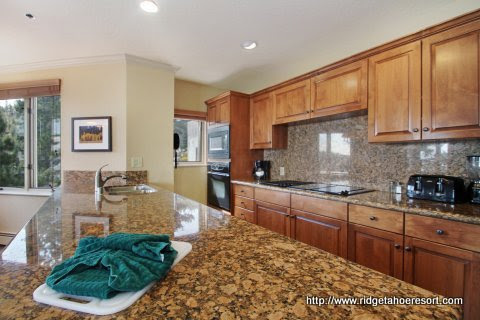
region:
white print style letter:
[305, 293, 311, 305]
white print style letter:
[315, 295, 326, 308]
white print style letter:
[332, 295, 342, 303]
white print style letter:
[340, 295, 350, 304]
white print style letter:
[348, 296, 358, 305]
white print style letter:
[454, 295, 462, 305]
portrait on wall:
[57, 106, 124, 158]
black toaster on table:
[393, 159, 472, 235]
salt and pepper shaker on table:
[377, 174, 415, 201]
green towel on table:
[41, 219, 206, 318]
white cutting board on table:
[21, 218, 202, 318]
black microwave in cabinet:
[194, 113, 245, 170]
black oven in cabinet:
[196, 160, 246, 225]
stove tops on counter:
[259, 165, 370, 228]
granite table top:
[4, 178, 479, 317]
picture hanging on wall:
[66, 111, 114, 152]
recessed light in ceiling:
[137, 0, 161, 21]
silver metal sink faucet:
[85, 159, 130, 190]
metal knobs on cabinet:
[410, 121, 433, 138]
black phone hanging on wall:
[172, 129, 180, 167]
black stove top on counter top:
[261, 174, 374, 202]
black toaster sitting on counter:
[401, 170, 463, 207]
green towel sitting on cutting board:
[51, 223, 174, 296]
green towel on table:
[78, 213, 219, 315]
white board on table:
[101, 220, 187, 304]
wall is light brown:
[86, 57, 140, 94]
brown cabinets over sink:
[337, 37, 457, 128]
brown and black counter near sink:
[385, 176, 413, 219]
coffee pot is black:
[254, 154, 284, 179]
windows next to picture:
[1, 77, 73, 197]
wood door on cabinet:
[245, 92, 272, 159]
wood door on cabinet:
[318, 59, 368, 115]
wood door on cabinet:
[373, 35, 421, 176]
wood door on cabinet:
[429, 40, 474, 145]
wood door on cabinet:
[246, 187, 292, 233]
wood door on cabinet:
[290, 181, 353, 244]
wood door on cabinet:
[348, 208, 405, 277]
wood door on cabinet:
[403, 216, 462, 304]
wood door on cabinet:
[218, 95, 230, 118]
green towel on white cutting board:
[46, 226, 183, 297]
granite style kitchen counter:
[2, 167, 464, 318]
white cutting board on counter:
[25, 234, 198, 317]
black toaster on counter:
[401, 170, 468, 206]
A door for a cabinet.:
[346, 223, 408, 293]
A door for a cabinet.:
[291, 202, 352, 261]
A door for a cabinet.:
[248, 198, 296, 239]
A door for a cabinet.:
[270, 74, 317, 124]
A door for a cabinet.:
[311, 61, 379, 123]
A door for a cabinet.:
[417, 16, 478, 122]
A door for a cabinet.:
[241, 88, 280, 168]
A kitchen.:
[18, 26, 478, 317]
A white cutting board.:
[30, 226, 198, 316]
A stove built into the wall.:
[205, 131, 233, 218]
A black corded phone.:
[169, 131, 183, 174]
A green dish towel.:
[43, 221, 178, 295]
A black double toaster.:
[397, 168, 460, 205]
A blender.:
[468, 155, 478, 204]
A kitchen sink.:
[96, 161, 159, 200]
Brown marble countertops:
[4, 159, 478, 317]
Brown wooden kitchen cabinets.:
[183, 11, 479, 304]